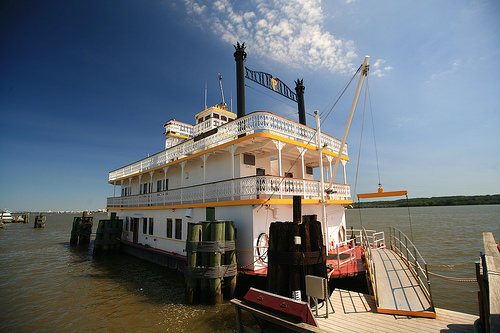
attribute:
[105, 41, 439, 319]
boat — at port, trimmed, white, yellow-trimmed, large, docked, yellow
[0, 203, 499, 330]
water — murky, green, calm, large, brown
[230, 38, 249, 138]
post — black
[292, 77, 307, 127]
post — black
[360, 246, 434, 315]
entrance ramp — tan, grey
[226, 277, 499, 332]
dock — wooden, brown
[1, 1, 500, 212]
sky — blue, beautiful, clear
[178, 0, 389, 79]
clouds — white, wispy, thin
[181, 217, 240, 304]
poles — tied, docking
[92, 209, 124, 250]
poles — tied, docking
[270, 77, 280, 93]
letter — yellow, large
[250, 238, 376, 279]
deck — red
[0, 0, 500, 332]
photo — outdoors